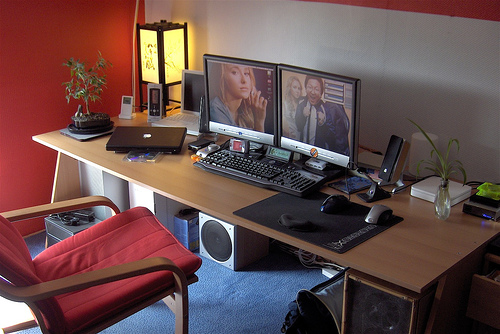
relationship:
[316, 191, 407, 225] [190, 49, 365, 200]
mice for computers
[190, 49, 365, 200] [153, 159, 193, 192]
computers on top of desk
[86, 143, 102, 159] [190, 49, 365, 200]
work station has computers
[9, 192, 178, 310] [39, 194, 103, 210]
chair has wooden handles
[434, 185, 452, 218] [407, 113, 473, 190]
vase with plant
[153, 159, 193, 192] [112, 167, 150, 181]
desk made of wood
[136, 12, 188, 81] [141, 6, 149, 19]
lamp in corner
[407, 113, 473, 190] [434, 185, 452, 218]
plant with vase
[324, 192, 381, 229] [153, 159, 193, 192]
computer mice on desk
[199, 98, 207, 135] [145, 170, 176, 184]
speaker underneath table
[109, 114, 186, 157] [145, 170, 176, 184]
laptop on table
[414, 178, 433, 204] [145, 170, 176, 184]
router on top of table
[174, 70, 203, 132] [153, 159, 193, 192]
computer set up on desk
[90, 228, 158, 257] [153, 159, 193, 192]
seat in front of desk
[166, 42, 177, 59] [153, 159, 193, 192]
light on top of desk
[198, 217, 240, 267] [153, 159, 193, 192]
speaker under desk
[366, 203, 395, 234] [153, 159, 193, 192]
mouse on top of desk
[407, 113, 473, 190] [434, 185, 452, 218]
plant in a vase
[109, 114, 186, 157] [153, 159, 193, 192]
laptop on desk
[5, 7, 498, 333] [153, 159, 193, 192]
room has desk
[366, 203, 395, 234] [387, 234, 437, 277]
mouse on counter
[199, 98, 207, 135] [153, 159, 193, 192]
speaker under desk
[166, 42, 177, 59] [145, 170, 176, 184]
light on top of table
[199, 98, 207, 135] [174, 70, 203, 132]
speaker near computer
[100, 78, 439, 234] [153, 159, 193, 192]
items around desk